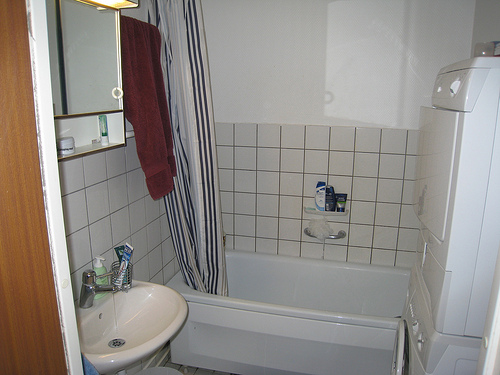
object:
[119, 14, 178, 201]
towel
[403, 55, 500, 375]
dryer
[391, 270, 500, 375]
washing machine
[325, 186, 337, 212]
shampoo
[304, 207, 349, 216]
shelf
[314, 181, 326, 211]
body wash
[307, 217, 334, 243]
loofa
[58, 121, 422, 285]
tiles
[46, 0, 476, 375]
walls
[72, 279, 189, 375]
sink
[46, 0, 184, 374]
wall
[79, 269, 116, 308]
faucet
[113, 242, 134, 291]
toothpaste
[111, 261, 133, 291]
cup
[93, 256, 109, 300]
liquid soap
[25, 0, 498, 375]
bathroom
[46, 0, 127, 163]
medicine cabinet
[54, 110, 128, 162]
shelf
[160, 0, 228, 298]
shower curtain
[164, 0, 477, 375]
shower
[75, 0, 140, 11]
light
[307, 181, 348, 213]
soaps